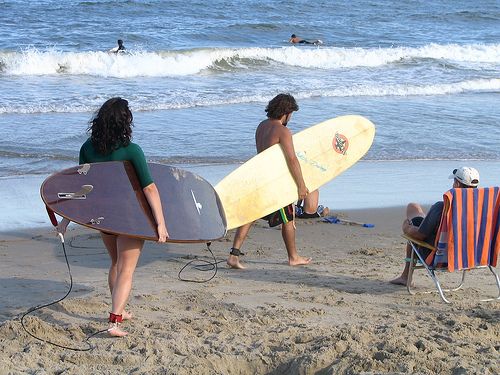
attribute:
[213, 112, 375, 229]
surfboard — white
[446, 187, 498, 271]
towel — striped, hanging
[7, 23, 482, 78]
waves — white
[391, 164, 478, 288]
man — sitting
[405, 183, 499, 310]
chair — beach chair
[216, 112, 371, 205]
surfboards — white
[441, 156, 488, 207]
cap — white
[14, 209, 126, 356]
bracelet — ankle bracelet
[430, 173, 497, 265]
striped towel — red, blue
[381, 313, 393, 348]
sand — kicked-up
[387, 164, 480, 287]
person — sitting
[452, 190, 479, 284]
towel — orange, blue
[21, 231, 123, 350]
leash — tied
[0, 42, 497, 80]
wave — crashing, huge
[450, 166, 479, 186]
cap — white 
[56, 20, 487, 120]
waves — white